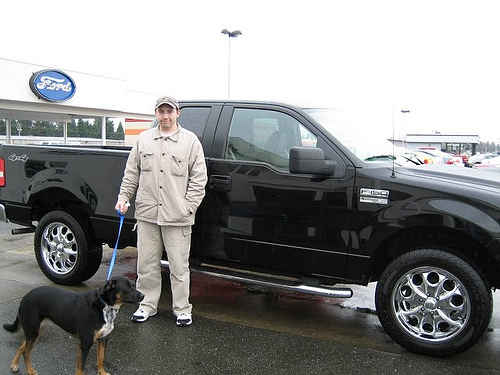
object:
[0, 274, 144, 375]
dog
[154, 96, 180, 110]
hat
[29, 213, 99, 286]
tire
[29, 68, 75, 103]
logo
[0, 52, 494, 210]
building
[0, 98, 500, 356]
truck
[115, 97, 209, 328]
man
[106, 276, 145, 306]
head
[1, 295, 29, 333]
tail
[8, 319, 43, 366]
leg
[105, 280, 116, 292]
ear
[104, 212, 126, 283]
leash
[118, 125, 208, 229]
jacket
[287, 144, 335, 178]
mirror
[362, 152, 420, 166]
windshield wiper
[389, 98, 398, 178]
antenna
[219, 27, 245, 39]
lights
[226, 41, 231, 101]
pole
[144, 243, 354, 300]
side step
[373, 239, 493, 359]
rims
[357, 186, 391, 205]
emblems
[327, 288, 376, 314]
puddle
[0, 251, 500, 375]
ground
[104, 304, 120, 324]
spots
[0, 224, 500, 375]
parking lot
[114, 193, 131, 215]
man's hand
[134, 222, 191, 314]
pants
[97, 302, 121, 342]
patch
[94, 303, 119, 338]
area